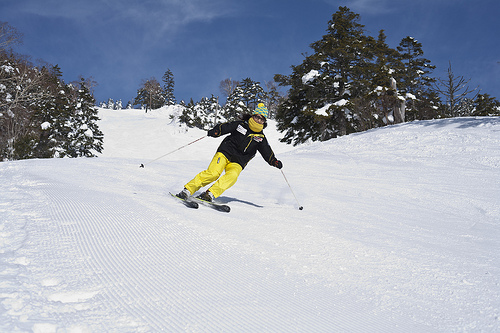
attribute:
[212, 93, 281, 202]
woman — skiing, active, here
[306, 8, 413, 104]
tree — standing, green, close, here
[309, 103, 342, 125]
snow — white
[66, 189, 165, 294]
ground — white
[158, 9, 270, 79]
sky — above, here, close, sunny, light, blue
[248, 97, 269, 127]
cap — Toboggan 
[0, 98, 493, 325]
slope — Downhill 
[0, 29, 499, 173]
trees — Evergreen 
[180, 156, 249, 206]
pants — yellow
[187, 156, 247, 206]
pants — yellow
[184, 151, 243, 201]
pants — yellow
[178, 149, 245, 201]
pants — yellow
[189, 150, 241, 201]
pants — yellow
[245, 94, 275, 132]
hat — yellow, green 